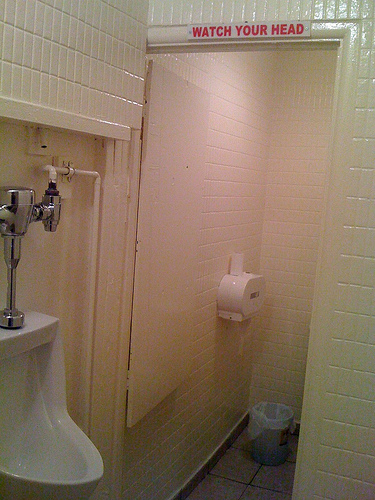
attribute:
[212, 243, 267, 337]
toilet paper holder — white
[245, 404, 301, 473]
waste can — blue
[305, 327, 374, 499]
tiles — white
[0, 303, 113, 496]
urinal — porcelain, white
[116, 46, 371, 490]
stall — white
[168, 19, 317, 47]
sign — white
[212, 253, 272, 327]
toilet paper — white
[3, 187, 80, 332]
fixture — chrome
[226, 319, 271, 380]
tissue — white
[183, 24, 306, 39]
letters — red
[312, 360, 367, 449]
tile — white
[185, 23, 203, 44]
"w" — red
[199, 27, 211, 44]
"a" — red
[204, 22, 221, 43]
"t" — red